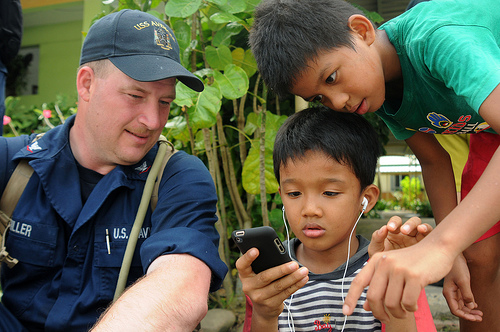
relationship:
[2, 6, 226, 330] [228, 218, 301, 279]
sailor looking phone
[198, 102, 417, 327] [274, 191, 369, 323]
boy wearing earbuds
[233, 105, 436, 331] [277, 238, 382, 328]
boy in shirt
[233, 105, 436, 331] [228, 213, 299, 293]
boy looking at phone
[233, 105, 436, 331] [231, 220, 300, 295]
boy looking phone